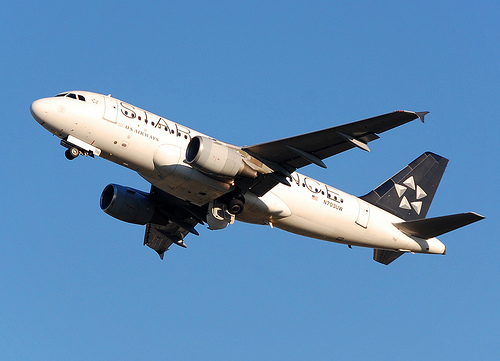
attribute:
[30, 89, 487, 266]
plane — large, big, very large, in the air, white color, huge, very white, flying, white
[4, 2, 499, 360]
sky — blue, blue colored, very blue, clear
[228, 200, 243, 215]
wheel — down, black colored, black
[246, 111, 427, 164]
wing — sharp, silver, gray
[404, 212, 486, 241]
back wing — blue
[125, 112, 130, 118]
window — small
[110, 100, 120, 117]
door — small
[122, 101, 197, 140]
logo — large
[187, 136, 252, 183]
engine — gray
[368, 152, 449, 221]
tail — upright, gray